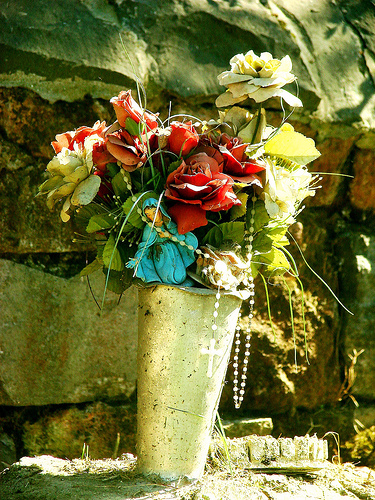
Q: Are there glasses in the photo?
A: No, there are no glasses.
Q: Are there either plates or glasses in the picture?
A: No, there are no glasses or plates.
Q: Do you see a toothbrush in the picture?
A: No, there are no toothbrushes.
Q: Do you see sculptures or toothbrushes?
A: No, there are no toothbrushes or sculptures.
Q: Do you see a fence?
A: No, there are no fences.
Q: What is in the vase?
A: The flower is in the vase.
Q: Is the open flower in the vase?
A: Yes, the flower is in the vase.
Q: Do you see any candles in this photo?
A: No, there are no candles.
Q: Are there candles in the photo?
A: No, there are no candles.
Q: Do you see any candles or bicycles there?
A: No, there are no candles or bicycles.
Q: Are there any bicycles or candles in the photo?
A: No, there are no candles or bicycles.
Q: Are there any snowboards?
A: No, there are no snowboards.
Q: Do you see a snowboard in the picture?
A: No, there are no snowboards.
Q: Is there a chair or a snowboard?
A: No, there are no snowboards or chairs.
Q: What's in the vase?
A: The flower is in the vase.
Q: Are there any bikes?
A: No, there are no bikes.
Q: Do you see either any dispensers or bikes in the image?
A: No, there are no bikes or dispensers.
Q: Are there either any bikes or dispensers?
A: No, there are no bikes or dispensers.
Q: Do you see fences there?
A: No, there are no fences.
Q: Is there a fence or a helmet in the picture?
A: No, there are no fences or helmets.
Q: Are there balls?
A: No, there are no balls.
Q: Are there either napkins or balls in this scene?
A: No, there are no balls or napkins.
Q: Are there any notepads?
A: No, there are no notepads.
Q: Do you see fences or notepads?
A: No, there are no notepads or fences.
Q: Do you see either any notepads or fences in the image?
A: No, there are no notepads or fences.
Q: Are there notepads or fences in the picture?
A: No, there are no notepads or fences.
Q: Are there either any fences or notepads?
A: No, there are no notepads or fences.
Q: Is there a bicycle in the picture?
A: No, there are no bicycles.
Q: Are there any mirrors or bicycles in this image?
A: No, there are no bicycles or mirrors.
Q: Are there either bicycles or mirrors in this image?
A: No, there are no bicycles or mirrors.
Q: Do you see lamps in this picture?
A: No, there are no lamps.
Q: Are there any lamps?
A: No, there are no lamps.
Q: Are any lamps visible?
A: No, there are no lamps.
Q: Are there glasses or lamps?
A: No, there are no lamps or glasses.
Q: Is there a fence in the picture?
A: No, there are no fences.